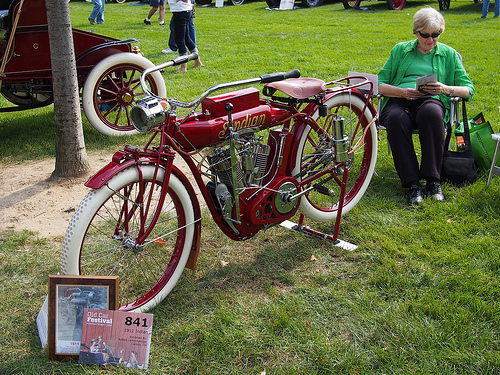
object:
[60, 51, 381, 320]
bike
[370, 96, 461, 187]
chair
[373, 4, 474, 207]
lady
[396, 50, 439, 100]
tshirt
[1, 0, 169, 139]
car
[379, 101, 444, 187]
pants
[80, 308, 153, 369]
book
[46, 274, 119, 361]
frame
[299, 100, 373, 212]
rim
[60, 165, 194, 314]
tire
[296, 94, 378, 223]
tire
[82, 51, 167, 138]
tire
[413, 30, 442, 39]
sunglasses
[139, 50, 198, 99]
handle bars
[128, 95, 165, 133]
headlight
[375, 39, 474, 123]
shirt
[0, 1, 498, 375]
grass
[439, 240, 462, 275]
green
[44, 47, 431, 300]
bike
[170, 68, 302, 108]
long handlebars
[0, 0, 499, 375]
field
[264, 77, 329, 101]
bicycle seat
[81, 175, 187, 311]
rim